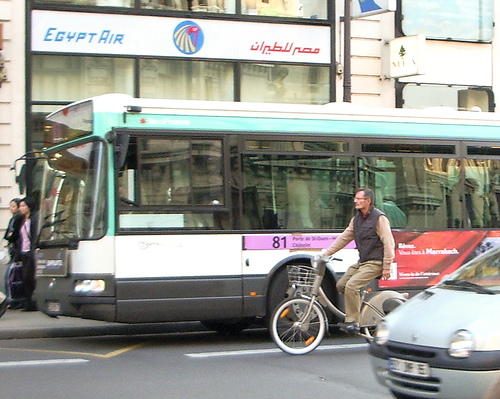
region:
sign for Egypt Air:
[22, 5, 364, 77]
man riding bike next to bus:
[263, 182, 420, 359]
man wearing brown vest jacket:
[349, 186, 395, 276]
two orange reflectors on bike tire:
[270, 286, 331, 356]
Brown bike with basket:
[261, 251, 423, 363]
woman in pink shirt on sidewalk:
[16, 194, 45, 314]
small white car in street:
[365, 240, 493, 393]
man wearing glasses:
[335, 178, 396, 239]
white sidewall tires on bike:
[271, 292, 401, 359]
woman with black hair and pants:
[16, 188, 43, 316]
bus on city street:
[29, 88, 493, 344]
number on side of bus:
[259, 221, 297, 256]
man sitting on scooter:
[267, 181, 403, 363]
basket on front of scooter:
[280, 255, 327, 297]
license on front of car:
[375, 353, 433, 382]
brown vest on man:
[344, 204, 389, 272]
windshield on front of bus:
[29, 134, 119, 255]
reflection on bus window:
[402, 149, 488, 223]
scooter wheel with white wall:
[262, 297, 333, 364]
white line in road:
[176, 337, 252, 372]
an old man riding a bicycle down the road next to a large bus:
[257, 168, 431, 357]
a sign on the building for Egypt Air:
[28, 3, 332, 73]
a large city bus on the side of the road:
[36, 96, 498, 324]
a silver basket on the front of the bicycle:
[286, 262, 323, 293]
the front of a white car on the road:
[368, 236, 499, 388]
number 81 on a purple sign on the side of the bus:
[263, 232, 293, 257]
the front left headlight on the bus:
[66, 268, 107, 296]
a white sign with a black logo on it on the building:
[387, 33, 426, 89]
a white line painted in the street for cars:
[3, 353, 93, 375]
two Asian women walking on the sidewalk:
[6, 189, 39, 305]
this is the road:
[139, 357, 336, 397]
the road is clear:
[111, 362, 281, 394]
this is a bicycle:
[271, 248, 408, 352]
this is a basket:
[282, 260, 320, 289]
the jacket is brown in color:
[356, 222, 373, 254]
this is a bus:
[41, 97, 493, 317]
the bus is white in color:
[154, 241, 210, 267]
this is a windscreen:
[41, 150, 105, 249]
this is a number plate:
[391, 357, 431, 379]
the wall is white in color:
[356, 35, 369, 96]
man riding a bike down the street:
[261, 168, 423, 357]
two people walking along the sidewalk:
[3, 196, 41, 314]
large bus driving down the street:
[30, 91, 497, 332]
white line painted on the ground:
[1, 351, 91, 371]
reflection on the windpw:
[421, 154, 499, 177]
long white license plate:
[388, 352, 433, 379]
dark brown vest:
[347, 212, 387, 262]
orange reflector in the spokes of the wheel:
[298, 333, 317, 345]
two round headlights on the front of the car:
[366, 316, 486, 361]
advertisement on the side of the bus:
[371, 226, 498, 288]